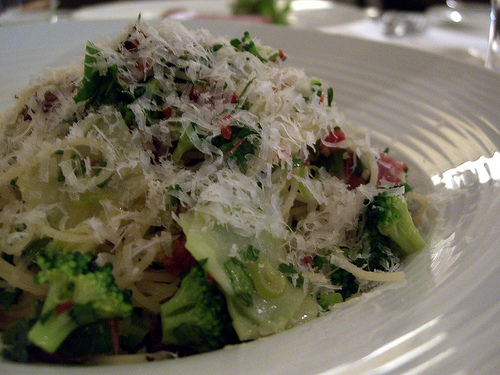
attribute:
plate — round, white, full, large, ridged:
[1, 17, 499, 375]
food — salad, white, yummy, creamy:
[1, 14, 430, 367]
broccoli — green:
[24, 256, 130, 355]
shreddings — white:
[7, 12, 343, 184]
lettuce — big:
[178, 217, 323, 339]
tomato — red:
[370, 153, 409, 185]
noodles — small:
[118, 274, 181, 311]